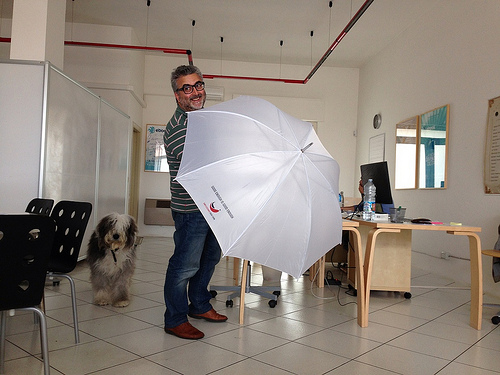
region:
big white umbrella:
[171, 91, 348, 281]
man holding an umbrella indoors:
[160, 65, 345, 342]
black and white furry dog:
[82, 209, 140, 311]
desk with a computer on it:
[335, 160, 486, 331]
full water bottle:
[360, 177, 377, 220]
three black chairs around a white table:
[1, 199, 94, 373]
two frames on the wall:
[392, 101, 449, 192]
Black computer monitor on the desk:
[355, 160, 399, 212]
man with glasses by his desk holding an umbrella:
[164, 62, 498, 342]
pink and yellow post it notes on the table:
[429, 218, 463, 228]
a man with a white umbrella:
[157, 59, 348, 346]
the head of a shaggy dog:
[98, 210, 138, 254]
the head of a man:
[166, 59, 210, 114]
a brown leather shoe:
[160, 314, 205, 345]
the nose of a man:
[190, 83, 204, 100]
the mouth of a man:
[188, 94, 209, 107]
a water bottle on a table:
[357, 178, 378, 220]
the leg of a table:
[464, 225, 486, 335]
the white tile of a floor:
[252, 323, 378, 373]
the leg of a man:
[160, 223, 210, 326]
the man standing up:
[162, 64, 227, 339]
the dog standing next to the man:
[87, 211, 137, 308]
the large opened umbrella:
[171, 97, 343, 283]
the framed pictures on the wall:
[393, 103, 450, 189]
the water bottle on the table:
[362, 179, 374, 220]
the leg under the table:
[447, 230, 482, 331]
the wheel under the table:
[404, 290, 411, 299]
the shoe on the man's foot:
[162, 322, 204, 341]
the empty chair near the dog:
[43, 199, 93, 344]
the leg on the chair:
[50, 273, 80, 343]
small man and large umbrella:
[162, 64, 344, 339]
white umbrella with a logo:
[174, 96, 345, 279]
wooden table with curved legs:
[346, 215, 482, 325]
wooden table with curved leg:
[339, 222, 362, 324]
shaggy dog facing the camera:
[85, 212, 137, 311]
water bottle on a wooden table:
[362, 178, 374, 216]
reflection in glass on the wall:
[395, 107, 447, 187]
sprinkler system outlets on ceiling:
[147, 0, 334, 50]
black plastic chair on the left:
[0, 214, 50, 367]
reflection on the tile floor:
[279, 272, 305, 339]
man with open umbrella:
[145, 25, 345, 330]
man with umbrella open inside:
[90, 56, 365, 366]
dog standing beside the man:
[90, 200, 151, 306]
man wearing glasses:
[110, 56, 325, 368]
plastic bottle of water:
[346, 176, 376, 206]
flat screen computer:
[360, 150, 422, 220]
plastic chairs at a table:
[0, 195, 86, 351]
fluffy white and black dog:
[83, 180, 146, 318]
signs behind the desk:
[394, 93, 464, 198]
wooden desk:
[279, 138, 423, 328]